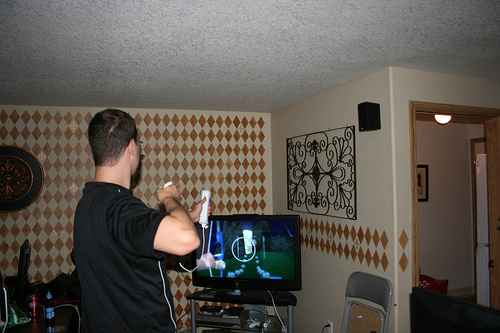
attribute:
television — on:
[187, 212, 307, 292]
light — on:
[433, 113, 455, 127]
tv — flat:
[177, 210, 307, 310]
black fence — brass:
[0, 151, 50, 213]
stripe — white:
[157, 259, 182, 331]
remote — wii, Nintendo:
[195, 185, 216, 230]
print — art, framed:
[417, 160, 432, 205]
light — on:
[418, 97, 465, 132]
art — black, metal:
[288, 159, 360, 216]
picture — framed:
[388, 151, 469, 203]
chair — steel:
[319, 264, 406, 328]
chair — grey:
[341, 266, 399, 331]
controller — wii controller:
[154, 171, 205, 246]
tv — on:
[188, 212, 301, 304]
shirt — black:
[72, 182, 183, 319]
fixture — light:
[435, 114, 453, 125]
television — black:
[140, 192, 316, 299]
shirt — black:
[72, 189, 173, 329]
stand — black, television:
[184, 290, 297, 330]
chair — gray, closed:
[337, 271, 394, 330]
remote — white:
[200, 190, 213, 229]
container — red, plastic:
[412, 264, 440, 289]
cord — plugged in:
[317, 319, 330, 332]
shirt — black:
[68, 179, 180, 331]